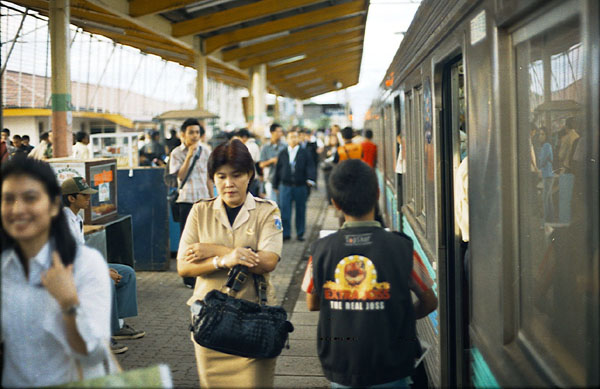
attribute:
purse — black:
[186, 265, 293, 358]